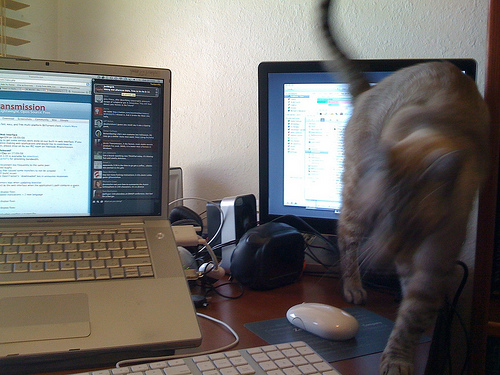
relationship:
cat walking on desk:
[307, 7, 479, 370] [4, 229, 496, 374]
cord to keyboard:
[113, 310, 240, 367] [77, 337, 341, 373]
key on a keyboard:
[296, 344, 315, 356] [57, 339, 349, 374]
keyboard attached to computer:
[68, 341, 343, 373] [0, 59, 203, 367]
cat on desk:
[315, 0, 493, 375] [4, 229, 496, 374]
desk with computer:
[0, 263, 500, 373] [0, 52, 199, 361]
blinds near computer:
[4, 0, 32, 57] [0, 59, 203, 367]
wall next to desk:
[50, 3, 293, 64] [144, 224, 356, 354]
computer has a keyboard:
[0, 59, 203, 367] [0, 235, 154, 285]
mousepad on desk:
[242, 302, 394, 364] [1, 264, 499, 373]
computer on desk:
[246, 57, 428, 242] [254, 285, 267, 306]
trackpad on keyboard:
[0, 292, 104, 343] [0, 205, 195, 336]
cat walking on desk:
[315, 0, 493, 375] [1, 264, 499, 373]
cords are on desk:
[175, 190, 469, 363] [0, 255, 449, 373]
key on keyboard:
[314, 361, 324, 372] [77, 337, 341, 373]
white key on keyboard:
[249, 336, 326, 373] [104, 333, 366, 373]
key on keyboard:
[289, 337, 306, 347] [77, 337, 341, 373]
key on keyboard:
[281, 342, 303, 362] [57, 339, 349, 374]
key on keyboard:
[266, 352, 281, 357] [126, 342, 331, 373]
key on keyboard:
[248, 348, 262, 356] [16, 219, 150, 293]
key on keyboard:
[223, 348, 241, 358] [77, 337, 341, 373]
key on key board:
[191, 354, 210, 363] [79, 340, 339, 373]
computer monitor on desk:
[254, 55, 484, 225] [33, 244, 463, 364]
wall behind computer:
[6, 3, 484, 221] [36, 59, 160, 271]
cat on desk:
[315, 0, 493, 375] [23, 211, 464, 370]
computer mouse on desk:
[286, 301, 360, 343] [184, 251, 469, 374]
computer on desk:
[0, 59, 203, 367] [231, 256, 357, 359]